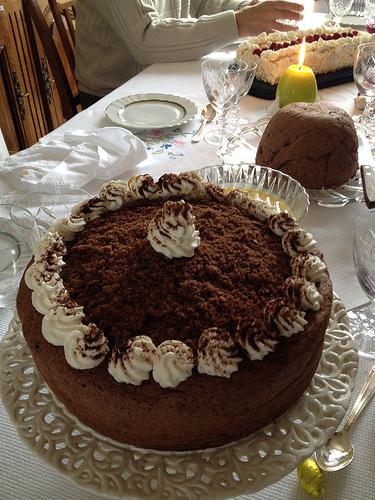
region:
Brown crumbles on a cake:
[54, 287, 96, 330]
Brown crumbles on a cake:
[82, 314, 114, 354]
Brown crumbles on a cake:
[106, 323, 141, 363]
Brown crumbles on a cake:
[136, 321, 171, 368]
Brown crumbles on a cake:
[164, 314, 212, 352]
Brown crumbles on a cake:
[195, 305, 253, 372]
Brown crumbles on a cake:
[212, 276, 260, 329]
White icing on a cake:
[181, 325, 236, 385]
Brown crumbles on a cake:
[92, 235, 131, 270]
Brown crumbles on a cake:
[196, 197, 278, 335]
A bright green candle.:
[276, 36, 318, 106]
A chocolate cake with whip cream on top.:
[14, 171, 334, 452]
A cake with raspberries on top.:
[236, 26, 373, 85]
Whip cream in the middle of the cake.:
[146, 196, 201, 258]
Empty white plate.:
[104, 92, 198, 130]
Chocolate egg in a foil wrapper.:
[296, 457, 330, 497]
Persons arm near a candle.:
[73, 0, 296, 62]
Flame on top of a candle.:
[297, 35, 306, 68]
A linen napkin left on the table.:
[0, 126, 147, 194]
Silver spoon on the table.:
[314, 367, 374, 472]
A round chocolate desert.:
[7, 159, 355, 470]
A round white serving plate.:
[4, 260, 361, 498]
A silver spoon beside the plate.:
[309, 353, 369, 476]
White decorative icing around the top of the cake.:
[22, 166, 338, 395]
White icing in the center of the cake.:
[141, 194, 204, 262]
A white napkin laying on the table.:
[0, 118, 148, 186]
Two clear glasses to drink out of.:
[194, 41, 259, 149]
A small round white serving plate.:
[103, 81, 199, 138]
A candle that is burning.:
[275, 30, 331, 102]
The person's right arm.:
[92, 1, 303, 57]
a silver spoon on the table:
[190, 100, 216, 147]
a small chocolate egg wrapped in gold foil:
[295, 456, 327, 497]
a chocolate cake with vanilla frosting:
[8, 164, 338, 456]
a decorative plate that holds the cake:
[0, 284, 360, 498]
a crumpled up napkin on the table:
[0, 120, 152, 200]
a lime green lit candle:
[276, 35, 321, 106]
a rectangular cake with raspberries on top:
[235, 20, 373, 90]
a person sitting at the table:
[69, 0, 306, 109]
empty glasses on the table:
[198, 54, 261, 147]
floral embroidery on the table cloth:
[129, 122, 203, 164]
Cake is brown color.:
[38, 193, 298, 420]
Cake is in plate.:
[110, 392, 254, 486]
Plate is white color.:
[162, 445, 302, 488]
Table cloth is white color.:
[137, 122, 240, 168]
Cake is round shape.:
[43, 187, 329, 391]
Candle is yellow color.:
[272, 43, 338, 108]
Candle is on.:
[264, 40, 331, 106]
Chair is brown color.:
[28, 13, 107, 99]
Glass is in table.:
[188, 42, 268, 150]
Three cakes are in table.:
[67, 14, 333, 464]